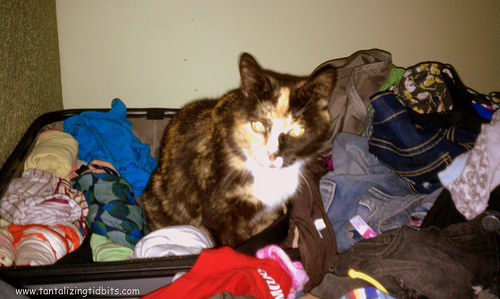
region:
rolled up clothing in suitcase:
[9, 88, 164, 274]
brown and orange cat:
[122, 47, 357, 284]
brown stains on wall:
[178, 48, 209, 95]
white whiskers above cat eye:
[289, 90, 325, 122]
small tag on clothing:
[343, 209, 388, 239]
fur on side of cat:
[173, 130, 220, 190]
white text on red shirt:
[245, 261, 290, 297]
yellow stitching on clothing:
[408, 135, 435, 162]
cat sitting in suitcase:
[42, 51, 363, 269]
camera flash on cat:
[228, 99, 317, 207]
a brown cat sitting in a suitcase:
[149, 39, 341, 253]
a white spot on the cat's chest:
[211, 39, 341, 214]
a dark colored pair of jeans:
[360, 49, 495, 201]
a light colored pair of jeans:
[319, 119, 439, 252]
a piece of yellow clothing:
[20, 109, 83, 181]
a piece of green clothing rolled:
[81, 208, 138, 263]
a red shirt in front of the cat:
[131, 235, 287, 297]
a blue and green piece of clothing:
[65, 158, 157, 247]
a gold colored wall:
[6, 6, 69, 154]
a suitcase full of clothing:
[21, 86, 310, 298]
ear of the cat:
[217, 39, 287, 109]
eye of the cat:
[238, 105, 279, 155]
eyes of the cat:
[240, 109, 312, 150]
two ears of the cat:
[215, 41, 360, 111]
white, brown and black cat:
[186, 62, 343, 210]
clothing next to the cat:
[301, 32, 491, 222]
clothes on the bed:
[335, 28, 490, 217]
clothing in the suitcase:
[15, 98, 172, 260]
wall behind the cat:
[83, 15, 218, 92]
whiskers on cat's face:
[202, 140, 281, 213]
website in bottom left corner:
[13, 267, 157, 297]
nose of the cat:
[251, 122, 298, 171]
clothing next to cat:
[339, 64, 464, 224]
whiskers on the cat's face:
[205, 142, 274, 209]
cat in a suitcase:
[103, 53, 353, 251]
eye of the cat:
[236, 108, 276, 144]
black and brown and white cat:
[155, 65, 327, 218]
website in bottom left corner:
[10, 268, 162, 298]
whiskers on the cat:
[207, 159, 262, 201]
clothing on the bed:
[296, 65, 483, 282]